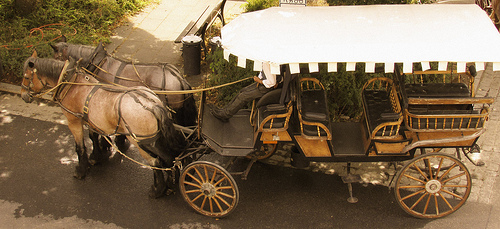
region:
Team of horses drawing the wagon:
[13, 31, 197, 180]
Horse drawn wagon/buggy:
[171, 9, 492, 222]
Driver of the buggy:
[200, 45, 295, 127]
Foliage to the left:
[1, 2, 136, 98]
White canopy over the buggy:
[211, 2, 498, 97]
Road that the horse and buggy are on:
[0, 117, 495, 227]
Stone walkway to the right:
[451, 45, 498, 205]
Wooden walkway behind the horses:
[115, 11, 220, 84]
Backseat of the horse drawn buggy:
[386, 69, 498, 144]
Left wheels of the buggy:
[166, 140, 491, 225]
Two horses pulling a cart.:
[18, 33, 200, 205]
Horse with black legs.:
[68, 134, 180, 200]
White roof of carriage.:
[209, 8, 499, 85]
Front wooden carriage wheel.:
[170, 154, 250, 218]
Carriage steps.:
[324, 168, 364, 208]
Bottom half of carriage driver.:
[208, 51, 286, 126]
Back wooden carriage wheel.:
[386, 149, 481, 221]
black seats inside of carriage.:
[296, 74, 492, 144]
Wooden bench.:
[171, 1, 230, 60]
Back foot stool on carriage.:
[462, 148, 489, 168]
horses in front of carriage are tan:
[32, 29, 189, 173]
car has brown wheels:
[183, 162, 230, 226]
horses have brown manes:
[23, 38, 107, 78]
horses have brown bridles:
[23, 43, 100, 111]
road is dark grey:
[28, 133, 110, 225]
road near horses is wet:
[12, 115, 98, 221]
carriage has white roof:
[223, 17, 499, 93]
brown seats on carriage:
[265, 82, 342, 170]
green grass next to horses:
[1, 8, 123, 50]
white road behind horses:
[117, 6, 192, 52]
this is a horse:
[11, 50, 174, 185]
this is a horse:
[45, 35, 210, 120]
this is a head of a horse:
[11, 50, 56, 105]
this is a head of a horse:
[40, 30, 92, 61]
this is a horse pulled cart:
[20, 0, 498, 216]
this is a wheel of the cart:
[176, 151, 236, 219]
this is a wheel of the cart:
[370, 151, 481, 224]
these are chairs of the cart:
[243, 75, 288, 150]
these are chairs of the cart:
[296, 72, 332, 148]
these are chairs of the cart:
[356, 64, 498, 152]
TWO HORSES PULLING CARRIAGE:
[24, 11, 464, 213]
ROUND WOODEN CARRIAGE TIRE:
[385, 143, 454, 225]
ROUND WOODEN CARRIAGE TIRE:
[168, 149, 249, 217]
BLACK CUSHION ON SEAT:
[303, 83, 328, 135]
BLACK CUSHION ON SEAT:
[358, 78, 395, 134]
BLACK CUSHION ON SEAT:
[259, 96, 288, 127]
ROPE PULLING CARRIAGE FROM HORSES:
[91, 61, 241, 98]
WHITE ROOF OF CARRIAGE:
[225, 6, 474, 79]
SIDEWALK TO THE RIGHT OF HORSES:
[109, 6, 190, 56]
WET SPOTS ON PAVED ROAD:
[2, 103, 224, 225]